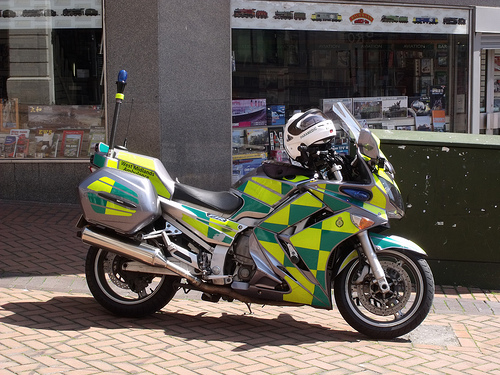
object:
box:
[430, 108, 446, 131]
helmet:
[280, 110, 338, 161]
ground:
[0, 196, 499, 374]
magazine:
[232, 101, 267, 117]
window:
[232, 27, 466, 122]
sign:
[348, 9, 375, 25]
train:
[232, 9, 270, 19]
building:
[0, 0, 478, 205]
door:
[474, 33, 500, 134]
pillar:
[100, 0, 235, 193]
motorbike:
[75, 101, 438, 340]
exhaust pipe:
[78, 225, 205, 291]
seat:
[174, 181, 245, 214]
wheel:
[333, 240, 437, 341]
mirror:
[359, 133, 378, 162]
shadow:
[0, 295, 410, 352]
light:
[86, 139, 113, 169]